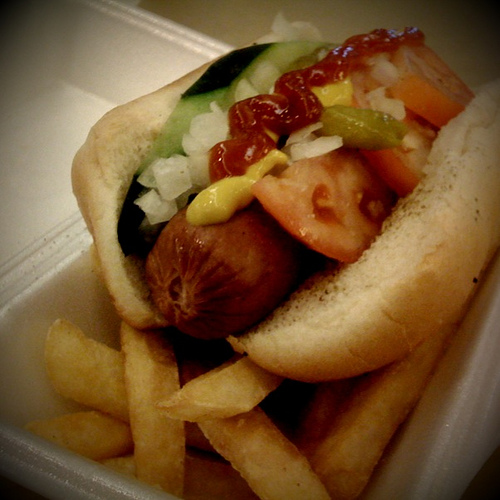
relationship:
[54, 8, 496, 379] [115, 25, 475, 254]
hot dog loaded with toppings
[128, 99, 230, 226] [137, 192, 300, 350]
onions on hot dog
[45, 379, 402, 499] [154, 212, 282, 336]
fries under hot dog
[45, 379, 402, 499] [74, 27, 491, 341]
fries under sandwich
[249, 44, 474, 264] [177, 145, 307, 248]
ketchup by mustard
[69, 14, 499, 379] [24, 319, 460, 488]
tablehot dogs by fries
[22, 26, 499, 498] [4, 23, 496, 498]
food in styrofoam box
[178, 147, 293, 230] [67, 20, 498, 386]
mustard on hotdog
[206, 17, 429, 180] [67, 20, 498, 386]
ketchup on hotdog